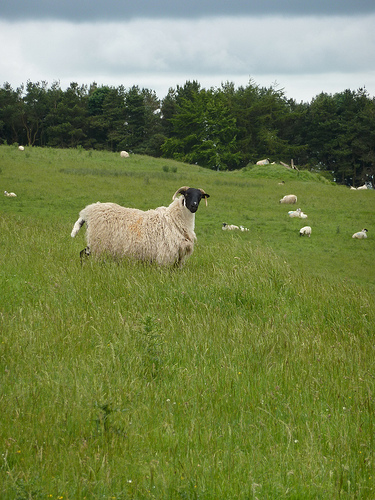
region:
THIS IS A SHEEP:
[59, 179, 220, 278]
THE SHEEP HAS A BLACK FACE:
[182, 182, 202, 218]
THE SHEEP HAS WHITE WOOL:
[69, 182, 207, 283]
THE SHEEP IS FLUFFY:
[55, 173, 224, 297]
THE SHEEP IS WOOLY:
[67, 184, 215, 298]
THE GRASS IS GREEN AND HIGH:
[0, 143, 373, 493]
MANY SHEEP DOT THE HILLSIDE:
[6, 138, 374, 281]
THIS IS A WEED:
[89, 384, 144, 475]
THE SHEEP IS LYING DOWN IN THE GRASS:
[220, 216, 255, 239]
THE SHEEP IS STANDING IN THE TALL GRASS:
[67, 178, 217, 274]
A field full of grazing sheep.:
[7, 133, 370, 274]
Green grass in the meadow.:
[15, 256, 362, 480]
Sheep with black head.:
[69, 185, 212, 270]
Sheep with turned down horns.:
[66, 178, 217, 274]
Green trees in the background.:
[2, 72, 371, 187]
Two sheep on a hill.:
[234, 154, 337, 191]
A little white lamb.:
[1, 184, 25, 201]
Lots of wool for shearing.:
[65, 184, 218, 275]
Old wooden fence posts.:
[277, 155, 304, 174]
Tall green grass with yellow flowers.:
[5, 342, 373, 498]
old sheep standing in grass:
[64, 157, 242, 301]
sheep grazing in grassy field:
[66, 144, 334, 294]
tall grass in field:
[88, 355, 265, 477]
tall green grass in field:
[81, 351, 277, 474]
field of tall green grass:
[60, 351, 212, 442]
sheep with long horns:
[73, 173, 244, 288]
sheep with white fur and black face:
[82, 168, 222, 278]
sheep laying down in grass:
[217, 213, 259, 241]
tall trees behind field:
[33, 56, 290, 185]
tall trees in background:
[15, 69, 373, 211]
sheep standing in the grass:
[64, 183, 215, 277]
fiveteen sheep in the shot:
[0, 142, 374, 279]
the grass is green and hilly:
[0, 141, 370, 494]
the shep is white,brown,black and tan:
[51, 180, 208, 278]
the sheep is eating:
[295, 219, 310, 234]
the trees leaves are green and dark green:
[0, 68, 368, 179]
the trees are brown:
[0, 65, 369, 179]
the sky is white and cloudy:
[0, 0, 370, 100]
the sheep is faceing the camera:
[65, 173, 207, 266]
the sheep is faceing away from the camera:
[348, 225, 368, 240]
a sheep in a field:
[70, 184, 208, 274]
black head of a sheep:
[177, 186, 209, 213]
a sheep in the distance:
[298, 225, 311, 235]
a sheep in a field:
[350, 225, 367, 239]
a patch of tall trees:
[2, 81, 373, 183]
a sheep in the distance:
[118, 150, 129, 157]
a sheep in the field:
[276, 191, 296, 204]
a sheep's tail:
[70, 211, 86, 237]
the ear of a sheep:
[201, 192, 209, 198]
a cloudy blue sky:
[0, 1, 373, 87]